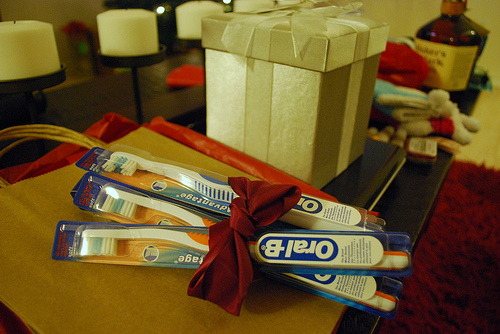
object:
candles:
[0, 2, 298, 91]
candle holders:
[7, 44, 212, 147]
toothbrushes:
[49, 143, 415, 320]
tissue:
[134, 108, 344, 205]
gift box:
[197, 6, 392, 192]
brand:
[257, 230, 336, 270]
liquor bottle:
[404, 4, 495, 107]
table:
[11, 75, 496, 333]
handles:
[0, 116, 111, 193]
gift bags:
[3, 129, 365, 333]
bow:
[217, 3, 370, 67]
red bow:
[178, 172, 307, 321]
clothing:
[375, 37, 436, 95]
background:
[52, 145, 109, 264]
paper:
[27, 186, 56, 228]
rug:
[381, 160, 497, 330]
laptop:
[320, 131, 411, 213]